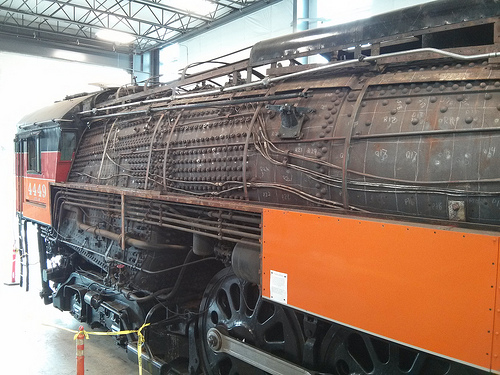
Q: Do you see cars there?
A: No, there are no cars.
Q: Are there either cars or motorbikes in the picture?
A: No, there are no cars or motorbikes.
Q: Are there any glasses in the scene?
A: No, there are no glasses.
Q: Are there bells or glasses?
A: No, there are no glasses or bells.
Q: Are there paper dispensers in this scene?
A: No, there are no paper dispensers.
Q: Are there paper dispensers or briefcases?
A: No, there are no paper dispensers or briefcases.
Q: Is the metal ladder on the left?
A: Yes, the ladder is on the left of the image.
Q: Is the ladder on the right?
A: No, the ladder is on the left of the image.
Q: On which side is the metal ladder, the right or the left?
A: The ladder is on the left of the image.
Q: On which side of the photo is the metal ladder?
A: The ladder is on the left of the image.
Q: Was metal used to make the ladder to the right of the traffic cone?
A: Yes, the ladder is made of metal.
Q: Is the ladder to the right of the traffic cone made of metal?
A: Yes, the ladder is made of metal.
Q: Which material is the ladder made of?
A: The ladder is made of metal.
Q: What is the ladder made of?
A: The ladder is made of metal.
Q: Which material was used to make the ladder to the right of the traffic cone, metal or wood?
A: The ladder is made of metal.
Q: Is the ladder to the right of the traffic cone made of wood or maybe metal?
A: The ladder is made of metal.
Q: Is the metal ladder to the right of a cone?
A: Yes, the ladder is to the right of a cone.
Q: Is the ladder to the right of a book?
A: No, the ladder is to the right of a cone.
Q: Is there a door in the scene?
A: Yes, there is a door.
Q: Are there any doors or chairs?
A: Yes, there is a door.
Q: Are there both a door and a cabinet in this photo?
A: No, there is a door but no cabinets.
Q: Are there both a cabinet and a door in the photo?
A: No, there is a door but no cabinets.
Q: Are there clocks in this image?
A: No, there are no clocks.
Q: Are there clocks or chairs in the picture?
A: No, there are no clocks or chairs.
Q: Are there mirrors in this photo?
A: No, there are no mirrors.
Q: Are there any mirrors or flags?
A: No, there are no mirrors or flags.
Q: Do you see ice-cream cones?
A: No, there are no ice-cream cones.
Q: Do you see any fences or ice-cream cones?
A: No, there are no ice-cream cones or fences.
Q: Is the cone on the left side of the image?
A: Yes, the cone is on the left of the image.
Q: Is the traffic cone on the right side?
A: No, the traffic cone is on the left of the image.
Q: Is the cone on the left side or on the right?
A: The cone is on the left of the image.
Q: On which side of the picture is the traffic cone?
A: The traffic cone is on the left of the image.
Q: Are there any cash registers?
A: No, there are no cash registers.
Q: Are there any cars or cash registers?
A: No, there are no cash registers or cars.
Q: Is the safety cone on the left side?
A: Yes, the safety cone is on the left of the image.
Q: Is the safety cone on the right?
A: No, the safety cone is on the left of the image.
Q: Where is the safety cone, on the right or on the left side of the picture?
A: The safety cone is on the left of the image.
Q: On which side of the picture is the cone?
A: The cone is on the left of the image.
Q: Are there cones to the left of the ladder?
A: Yes, there is a cone to the left of the ladder.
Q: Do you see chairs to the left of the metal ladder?
A: No, there is a cone to the left of the ladder.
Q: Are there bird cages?
A: No, there are no bird cages.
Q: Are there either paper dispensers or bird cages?
A: No, there are no bird cages or paper dispensers.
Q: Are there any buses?
A: No, there are no buses.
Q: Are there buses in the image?
A: No, there are no buses.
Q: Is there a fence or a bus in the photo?
A: No, there are no buses or fences.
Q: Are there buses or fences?
A: No, there are no buses or fences.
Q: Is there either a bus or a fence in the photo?
A: No, there are no buses or fences.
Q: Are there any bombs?
A: No, there are no bombs.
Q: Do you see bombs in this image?
A: No, there are no bombs.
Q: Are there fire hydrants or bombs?
A: No, there are no bombs or fire hydrants.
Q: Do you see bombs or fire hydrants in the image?
A: No, there are no bombs or fire hydrants.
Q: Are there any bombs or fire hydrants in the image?
A: No, there are no bombs or fire hydrants.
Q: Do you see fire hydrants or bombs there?
A: No, there are no bombs or fire hydrants.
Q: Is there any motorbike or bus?
A: No, there are no buses or motorcycles.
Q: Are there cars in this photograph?
A: No, there are no cars.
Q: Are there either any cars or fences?
A: No, there are no cars or fences.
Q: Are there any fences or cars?
A: No, there are no cars or fences.